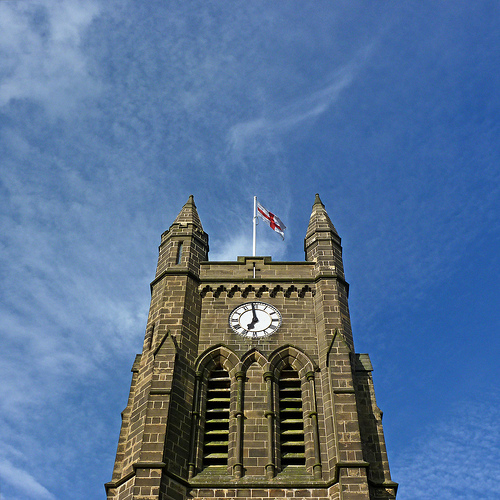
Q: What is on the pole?
A: A flag.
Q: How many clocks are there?
A: One.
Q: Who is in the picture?
A: Nobody.